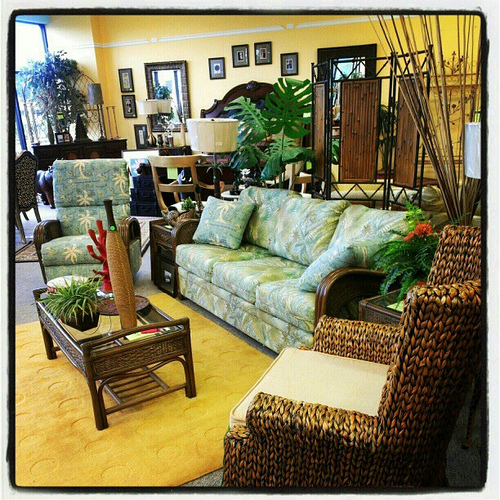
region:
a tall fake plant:
[232, 68, 310, 193]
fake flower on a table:
[363, 213, 448, 308]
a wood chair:
[144, 148, 204, 216]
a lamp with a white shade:
[191, 109, 246, 206]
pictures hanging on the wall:
[116, 60, 136, 122]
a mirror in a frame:
[139, 56, 191, 156]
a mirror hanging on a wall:
[135, 62, 192, 144]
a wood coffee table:
[18, 279, 218, 419]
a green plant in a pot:
[50, 275, 105, 331]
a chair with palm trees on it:
[22, 149, 137, 283]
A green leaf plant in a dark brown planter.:
[32, 276, 103, 332]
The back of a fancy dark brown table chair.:
[16, 150, 45, 243]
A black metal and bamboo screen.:
[308, 43, 435, 210]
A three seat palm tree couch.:
[175, 184, 432, 359]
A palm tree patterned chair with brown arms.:
[30, 160, 138, 285]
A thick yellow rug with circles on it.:
[16, 293, 273, 486]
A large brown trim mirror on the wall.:
[141, 59, 191, 131]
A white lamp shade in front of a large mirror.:
[135, 97, 160, 117]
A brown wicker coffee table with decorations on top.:
[31, 283, 198, 430]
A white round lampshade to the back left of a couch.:
[183, 117, 239, 154]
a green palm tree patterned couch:
[174, 195, 428, 352]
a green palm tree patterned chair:
[41, 153, 141, 298]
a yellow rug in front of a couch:
[14, 289, 276, 488]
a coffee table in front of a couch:
[29, 280, 203, 425]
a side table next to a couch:
[146, 204, 203, 305]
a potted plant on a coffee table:
[46, 279, 103, 334]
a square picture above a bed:
[230, 43, 250, 67]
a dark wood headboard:
[196, 80, 274, 120]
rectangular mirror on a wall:
[146, 56, 191, 136]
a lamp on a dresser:
[85, 80, 114, 145]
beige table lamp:
[169, 110, 278, 236]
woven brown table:
[35, 186, 216, 431]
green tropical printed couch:
[160, 172, 445, 369]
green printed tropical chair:
[30, 141, 150, 303]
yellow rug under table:
[13, 271, 255, 498]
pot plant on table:
[347, 192, 475, 325]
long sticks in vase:
[383, 12, 498, 222]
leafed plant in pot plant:
[213, 58, 344, 213]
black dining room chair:
[18, 142, 56, 264]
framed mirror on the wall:
[120, 42, 200, 157]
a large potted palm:
[216, 82, 317, 184]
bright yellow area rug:
[16, 252, 271, 495]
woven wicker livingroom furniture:
[224, 203, 484, 489]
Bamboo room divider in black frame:
[307, 57, 432, 209]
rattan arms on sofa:
[171, 208, 380, 326]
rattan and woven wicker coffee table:
[33, 282, 202, 422]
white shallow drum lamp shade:
[183, 114, 245, 160]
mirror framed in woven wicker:
[143, 59, 190, 131]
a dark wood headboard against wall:
[196, 74, 311, 127]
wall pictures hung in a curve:
[203, 39, 312, 81]